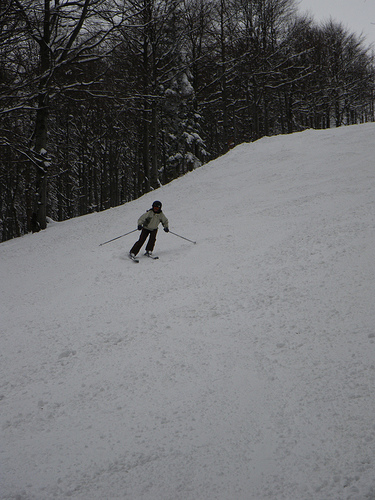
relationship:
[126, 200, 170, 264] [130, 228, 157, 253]
skier wears trousers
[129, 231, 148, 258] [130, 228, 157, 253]
leg of trousers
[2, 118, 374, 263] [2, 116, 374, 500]
slope white with snow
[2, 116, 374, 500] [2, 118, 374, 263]
snow covers slope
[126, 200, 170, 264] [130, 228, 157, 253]
skier wearing black trousers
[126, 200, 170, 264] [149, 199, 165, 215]
skier turns their head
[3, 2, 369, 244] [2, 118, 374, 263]
trees along slope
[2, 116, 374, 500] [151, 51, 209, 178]
snow on a tree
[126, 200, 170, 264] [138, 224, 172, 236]
skier wears gloves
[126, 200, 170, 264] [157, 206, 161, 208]
skier wears goggles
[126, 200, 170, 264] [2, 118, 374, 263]
skier skiing down a slope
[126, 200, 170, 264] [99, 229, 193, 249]
skier holds poles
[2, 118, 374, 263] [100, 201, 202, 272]
slope where skier skiing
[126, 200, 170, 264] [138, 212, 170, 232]
skier wearing a jacket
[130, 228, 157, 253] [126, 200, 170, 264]
trousers on skier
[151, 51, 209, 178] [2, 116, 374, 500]
tree covered with snow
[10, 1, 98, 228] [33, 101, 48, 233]
tree with thick trunk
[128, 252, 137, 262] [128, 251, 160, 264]
edge os skies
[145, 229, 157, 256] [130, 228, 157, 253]
leg of trousers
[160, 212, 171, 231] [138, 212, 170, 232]
arm of a jacket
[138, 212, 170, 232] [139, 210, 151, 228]
jacket on side